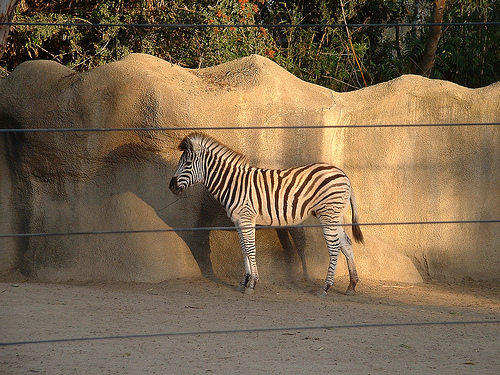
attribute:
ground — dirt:
[1, 274, 495, 372]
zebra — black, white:
[159, 133, 371, 291]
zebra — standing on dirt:
[169, 126, 368, 303]